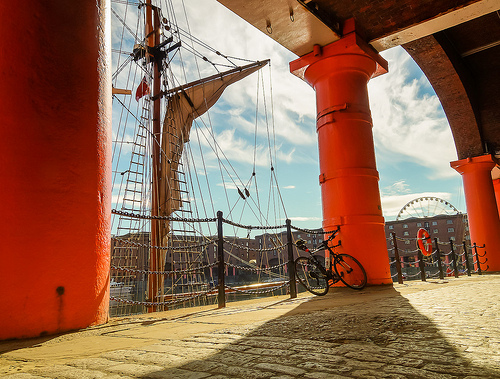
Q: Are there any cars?
A: No, there are no cars.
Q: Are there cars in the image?
A: No, there are no cars.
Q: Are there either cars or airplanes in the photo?
A: No, there are no cars or airplanes.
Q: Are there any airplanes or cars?
A: No, there are no cars or airplanes.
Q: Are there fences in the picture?
A: Yes, there is a fence.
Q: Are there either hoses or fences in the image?
A: Yes, there is a fence.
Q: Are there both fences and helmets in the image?
A: No, there is a fence but no helmets.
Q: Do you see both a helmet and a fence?
A: No, there is a fence but no helmets.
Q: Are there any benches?
A: No, there are no benches.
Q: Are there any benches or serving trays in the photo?
A: No, there are no benches or serving trays.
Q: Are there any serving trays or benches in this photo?
A: No, there are no benches or serving trays.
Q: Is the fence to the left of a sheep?
A: No, the fence is to the left of the life jacket.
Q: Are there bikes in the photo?
A: Yes, there is a bike.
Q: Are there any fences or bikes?
A: Yes, there is a bike.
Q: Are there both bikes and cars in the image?
A: No, there is a bike but no cars.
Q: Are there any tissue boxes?
A: No, there are no tissue boxes.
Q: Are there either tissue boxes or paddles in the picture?
A: No, there are no tissue boxes or paddles.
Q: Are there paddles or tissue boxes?
A: No, there are no tissue boxes or paddles.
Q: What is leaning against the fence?
A: The bike is leaning against the fence.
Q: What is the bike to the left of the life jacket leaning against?
A: The bike is leaning against the fence.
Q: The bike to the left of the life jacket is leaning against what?
A: The bike is leaning against the fence.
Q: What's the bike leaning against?
A: The bike is leaning against the fence.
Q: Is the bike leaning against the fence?
A: Yes, the bike is leaning against the fence.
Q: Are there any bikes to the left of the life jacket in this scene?
A: Yes, there is a bike to the left of the life jacket.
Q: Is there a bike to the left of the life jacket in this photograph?
A: Yes, there is a bike to the left of the life jacket.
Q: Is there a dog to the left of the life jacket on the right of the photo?
A: No, there is a bike to the left of the life vest.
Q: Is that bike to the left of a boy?
A: No, the bike is to the left of the life jacket.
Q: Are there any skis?
A: No, there are no skis.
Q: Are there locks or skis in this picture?
A: No, there are no skis or locks.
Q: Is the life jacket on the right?
A: Yes, the life jacket is on the right of the image.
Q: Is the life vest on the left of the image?
A: No, the life vest is on the right of the image.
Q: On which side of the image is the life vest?
A: The life vest is on the right of the image.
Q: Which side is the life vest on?
A: The life vest is on the right of the image.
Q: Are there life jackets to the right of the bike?
A: Yes, there is a life jacket to the right of the bike.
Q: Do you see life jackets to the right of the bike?
A: Yes, there is a life jacket to the right of the bike.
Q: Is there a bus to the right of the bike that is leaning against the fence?
A: No, there is a life jacket to the right of the bike.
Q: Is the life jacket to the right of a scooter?
A: No, the life jacket is to the right of the bike.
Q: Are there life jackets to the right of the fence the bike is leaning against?
A: Yes, there is a life jacket to the right of the fence.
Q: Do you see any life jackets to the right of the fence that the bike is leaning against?
A: Yes, there is a life jacket to the right of the fence.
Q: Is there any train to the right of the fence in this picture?
A: No, there is a life jacket to the right of the fence.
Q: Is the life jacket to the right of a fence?
A: Yes, the life jacket is to the right of a fence.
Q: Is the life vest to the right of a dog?
A: No, the life vest is to the right of a fence.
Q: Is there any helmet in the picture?
A: No, there are no helmets.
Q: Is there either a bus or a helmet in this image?
A: No, there are no helmets or buses.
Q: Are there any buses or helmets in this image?
A: No, there are no helmets or buses.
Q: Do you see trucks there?
A: No, there are no trucks.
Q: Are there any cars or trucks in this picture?
A: No, there are no trucks or cars.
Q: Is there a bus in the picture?
A: No, there are no buses.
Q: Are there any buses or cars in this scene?
A: No, there are no buses or cars.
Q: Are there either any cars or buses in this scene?
A: No, there are no buses or cars.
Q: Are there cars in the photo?
A: No, there are no cars.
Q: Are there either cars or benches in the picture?
A: No, there are no cars or benches.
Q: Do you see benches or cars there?
A: No, there are no cars or benches.